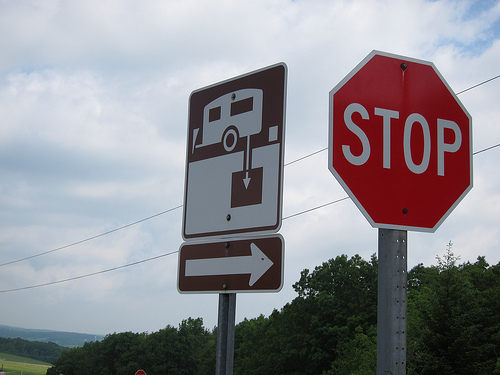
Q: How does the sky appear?
A: Cloudy.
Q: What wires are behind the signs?
A: Electrical wires.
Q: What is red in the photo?
A: Stop sign.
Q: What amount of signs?
A: Two.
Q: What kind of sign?
A: Stop.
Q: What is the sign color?
A: Brown.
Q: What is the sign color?
A: Red.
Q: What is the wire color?
A: Black.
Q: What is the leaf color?
A: Green.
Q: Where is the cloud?
A: Sky.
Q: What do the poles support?
A: Street sign.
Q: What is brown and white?
A: A street sign.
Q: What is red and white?
A: A street sign.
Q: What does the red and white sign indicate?
A: Stop.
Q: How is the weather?
A: Overcast.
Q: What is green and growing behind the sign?
A: A bush.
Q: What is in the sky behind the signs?
A: Electrical wires.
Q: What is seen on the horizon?
A: A mountain range.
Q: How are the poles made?
A: Of metal.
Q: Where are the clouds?
A: Sky.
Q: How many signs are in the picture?
A: Two.